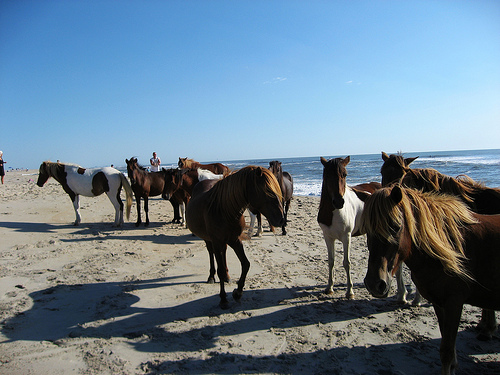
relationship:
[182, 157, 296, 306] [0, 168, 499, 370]
horse on sand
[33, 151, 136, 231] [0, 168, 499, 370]
horse on sand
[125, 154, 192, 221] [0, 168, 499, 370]
horse on sand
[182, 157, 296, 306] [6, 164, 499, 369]
horse at beach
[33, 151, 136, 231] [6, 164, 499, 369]
horse at beach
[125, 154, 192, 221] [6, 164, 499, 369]
horse at beach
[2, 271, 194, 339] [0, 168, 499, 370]
shadow in sand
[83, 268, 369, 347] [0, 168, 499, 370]
shadow in sand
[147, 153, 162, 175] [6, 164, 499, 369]
male on beach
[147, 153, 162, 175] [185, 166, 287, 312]
male behind horse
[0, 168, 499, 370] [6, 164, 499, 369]
sand on beach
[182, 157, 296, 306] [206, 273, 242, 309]
horse has hooves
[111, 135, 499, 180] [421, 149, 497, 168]
ocean has wave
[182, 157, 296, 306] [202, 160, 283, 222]
horse with mane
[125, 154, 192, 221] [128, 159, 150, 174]
horse with mane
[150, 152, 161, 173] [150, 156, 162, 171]
male in shirt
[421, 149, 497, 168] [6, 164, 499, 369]
wave near beach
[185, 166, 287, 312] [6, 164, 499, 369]
horse on beach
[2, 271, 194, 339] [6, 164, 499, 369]
shadow on beach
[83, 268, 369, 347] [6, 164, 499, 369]
shadow on beach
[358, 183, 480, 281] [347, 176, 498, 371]
mane on horse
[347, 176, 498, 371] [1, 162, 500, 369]
horse in foreground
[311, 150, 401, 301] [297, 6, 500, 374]
horse on side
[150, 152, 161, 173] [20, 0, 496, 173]
male in background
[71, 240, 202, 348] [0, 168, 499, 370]
track in sand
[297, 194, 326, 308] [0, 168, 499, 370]
track in sand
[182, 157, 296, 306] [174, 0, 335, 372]
horse in middle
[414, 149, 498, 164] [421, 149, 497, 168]
cap on wave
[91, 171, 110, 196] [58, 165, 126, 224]
spot on body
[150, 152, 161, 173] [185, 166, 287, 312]
male beyond horse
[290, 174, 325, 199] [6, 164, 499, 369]
foam near shore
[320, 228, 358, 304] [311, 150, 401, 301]
legs on horse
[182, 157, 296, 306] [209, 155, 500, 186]
horse looking toward water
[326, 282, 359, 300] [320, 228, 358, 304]
hooves on legs